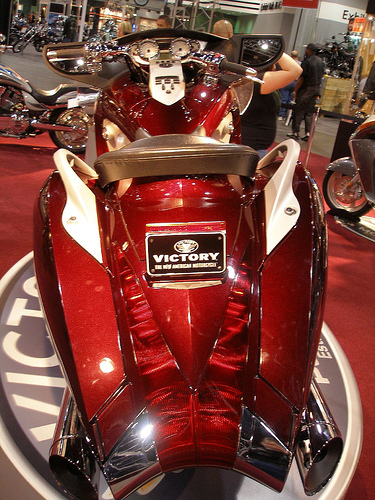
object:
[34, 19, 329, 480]
motorcycle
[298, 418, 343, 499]
exhaust pipe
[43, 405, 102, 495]
exhaust pipe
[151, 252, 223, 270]
name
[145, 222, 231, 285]
plate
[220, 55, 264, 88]
handle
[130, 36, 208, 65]
panel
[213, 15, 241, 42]
man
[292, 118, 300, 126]
black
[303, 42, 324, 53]
hat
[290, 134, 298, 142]
sneaker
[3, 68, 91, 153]
scooter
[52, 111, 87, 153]
tire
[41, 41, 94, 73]
mirror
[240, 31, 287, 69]
mirror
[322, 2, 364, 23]
sign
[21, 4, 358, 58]
hall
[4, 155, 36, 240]
carpet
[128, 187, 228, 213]
reflection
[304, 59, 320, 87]
shirt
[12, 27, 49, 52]
motorcycle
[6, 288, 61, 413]
exhibit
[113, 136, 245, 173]
seat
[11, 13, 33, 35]
group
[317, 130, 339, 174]
right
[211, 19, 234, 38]
head